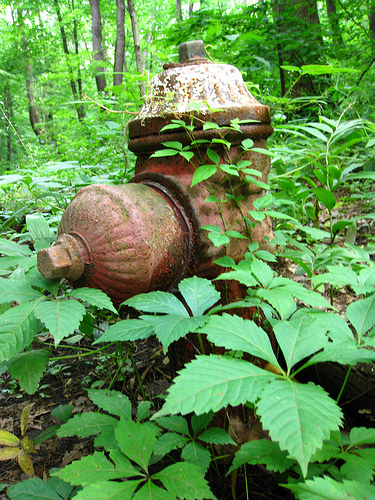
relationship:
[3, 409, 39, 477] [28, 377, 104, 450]
leaves on ground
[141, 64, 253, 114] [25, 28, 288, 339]
pant on hydrant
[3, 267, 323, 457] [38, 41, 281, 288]
plants almost covering hydrant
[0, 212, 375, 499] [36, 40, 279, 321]
weed around hydrant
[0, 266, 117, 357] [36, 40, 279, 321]
weed around hydrant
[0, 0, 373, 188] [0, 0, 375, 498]
trees in woods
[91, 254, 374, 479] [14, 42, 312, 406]
plants around fire hydrant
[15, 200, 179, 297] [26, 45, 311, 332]
valve on hydrant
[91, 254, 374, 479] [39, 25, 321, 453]
plants on hydrant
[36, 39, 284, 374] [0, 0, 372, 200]
fire hydrant in woods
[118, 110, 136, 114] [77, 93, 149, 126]
part of branch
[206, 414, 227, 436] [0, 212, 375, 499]
edge of weed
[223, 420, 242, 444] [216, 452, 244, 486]
part of root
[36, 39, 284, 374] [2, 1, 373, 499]
fire hydrant in woods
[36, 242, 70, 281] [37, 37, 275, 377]
bolt on hydrant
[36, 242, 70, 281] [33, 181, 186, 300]
bolt on cap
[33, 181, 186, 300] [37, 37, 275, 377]
cap on hydrant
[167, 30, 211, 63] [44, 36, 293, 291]
bolt on fire hydrant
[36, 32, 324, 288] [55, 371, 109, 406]
fire hydrant on ground